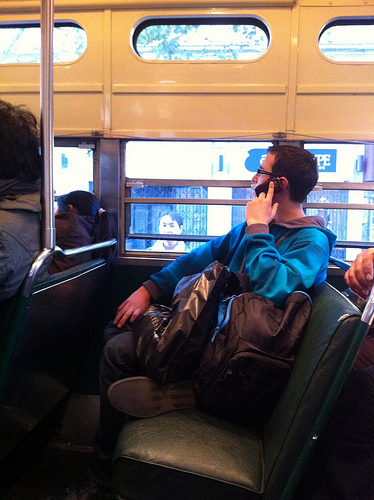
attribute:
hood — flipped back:
[282, 210, 341, 258]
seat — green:
[122, 422, 259, 497]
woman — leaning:
[49, 180, 120, 261]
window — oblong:
[137, 11, 288, 59]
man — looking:
[143, 210, 192, 252]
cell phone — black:
[253, 172, 286, 204]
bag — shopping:
[131, 259, 237, 384]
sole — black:
[105, 375, 202, 418]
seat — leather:
[108, 283, 363, 497]